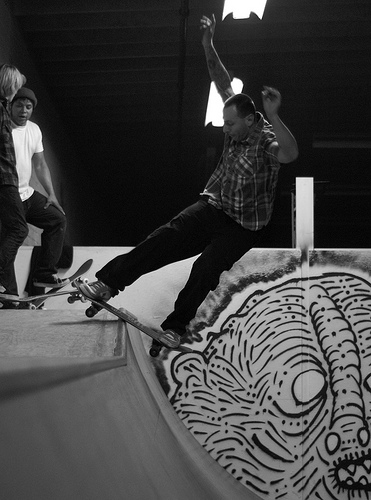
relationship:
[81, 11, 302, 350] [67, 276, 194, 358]
guy on skateboard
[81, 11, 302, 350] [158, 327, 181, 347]
guy wearing shoe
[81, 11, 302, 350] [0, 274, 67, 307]
guy wearing shoes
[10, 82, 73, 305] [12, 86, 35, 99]
guys wearing a beanie hat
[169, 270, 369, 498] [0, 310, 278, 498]
drawing on skate ramp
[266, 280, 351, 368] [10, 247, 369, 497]
graffiti on wall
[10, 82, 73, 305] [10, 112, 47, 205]
guys wearing shirt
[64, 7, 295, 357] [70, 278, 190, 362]
skater riding skateboard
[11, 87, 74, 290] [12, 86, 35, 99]
boy wearing beanie hat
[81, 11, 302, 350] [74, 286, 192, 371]
guy riding skateboard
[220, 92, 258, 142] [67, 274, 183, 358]
mans head looking at skateboard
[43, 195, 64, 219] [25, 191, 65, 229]
man`s hand placed on thigh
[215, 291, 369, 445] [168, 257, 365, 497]
drawing on wall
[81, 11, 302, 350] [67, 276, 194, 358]
guy on a skateboard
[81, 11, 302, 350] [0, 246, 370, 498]
guy skateboarding in rink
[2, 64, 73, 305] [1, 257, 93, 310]
guys on skateboard